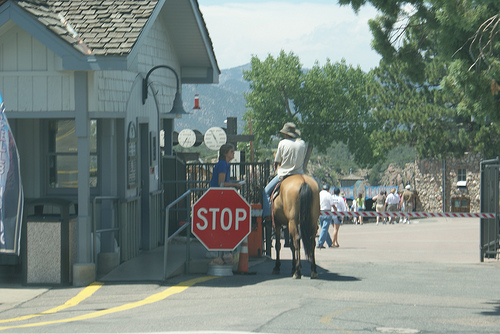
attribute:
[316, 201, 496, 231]
post — red, white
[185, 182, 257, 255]
sign — large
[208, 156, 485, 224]
wall — stone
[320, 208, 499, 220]
pole — red, white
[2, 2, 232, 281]
structure — grey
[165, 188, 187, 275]
hand railing — gray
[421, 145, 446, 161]
ground — white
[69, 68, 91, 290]
pole — curved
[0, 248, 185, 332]
lines — yellow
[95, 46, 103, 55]
shingle — gray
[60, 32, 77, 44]
shingle — gray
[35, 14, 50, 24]
shingle — gray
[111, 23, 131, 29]
shingle — gray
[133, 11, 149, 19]
shingle — gray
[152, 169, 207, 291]
railing — gray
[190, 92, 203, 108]
liquid — red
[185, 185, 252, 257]
sign — red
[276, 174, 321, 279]
horse — brown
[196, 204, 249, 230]
stop — white